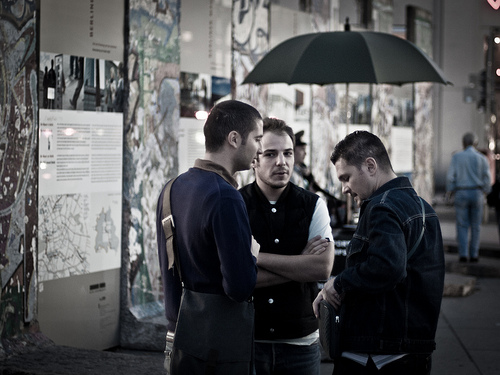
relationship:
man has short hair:
[161, 65, 263, 359] [202, 89, 262, 148]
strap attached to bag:
[148, 180, 201, 281] [170, 286, 257, 361]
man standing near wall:
[161, 65, 263, 359] [6, 3, 152, 362]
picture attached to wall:
[27, 105, 134, 276] [6, 3, 152, 362]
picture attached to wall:
[23, 35, 136, 112] [6, 3, 152, 362]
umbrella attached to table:
[242, 24, 469, 91] [330, 218, 363, 272]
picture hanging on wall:
[27, 105, 134, 276] [6, 3, 152, 362]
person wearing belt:
[441, 130, 493, 266] [447, 181, 487, 194]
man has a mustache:
[258, 114, 334, 369] [266, 165, 296, 177]